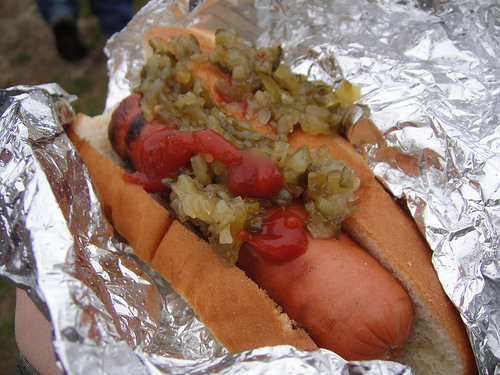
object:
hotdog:
[68, 25, 459, 373]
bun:
[68, 26, 482, 370]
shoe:
[53, 17, 89, 60]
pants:
[38, 2, 131, 23]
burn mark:
[123, 114, 144, 146]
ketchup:
[140, 132, 308, 257]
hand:
[12, 291, 50, 374]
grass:
[73, 79, 91, 94]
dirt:
[31, 59, 53, 79]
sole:
[59, 26, 80, 60]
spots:
[9, 52, 90, 88]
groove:
[147, 211, 173, 271]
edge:
[322, 272, 410, 358]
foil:
[3, 1, 498, 374]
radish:
[137, 37, 358, 238]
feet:
[55, 15, 132, 60]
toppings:
[138, 30, 360, 254]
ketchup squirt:
[134, 128, 282, 197]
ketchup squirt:
[238, 212, 308, 260]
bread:
[407, 324, 458, 374]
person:
[36, 1, 124, 59]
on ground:
[2, 1, 108, 85]